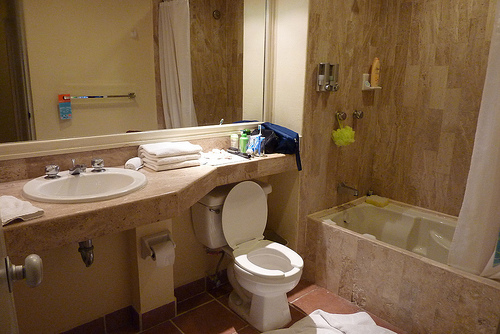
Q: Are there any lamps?
A: No, there are no lamps.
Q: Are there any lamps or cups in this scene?
A: No, there are no lamps or cups.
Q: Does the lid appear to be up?
A: Yes, the lid is up.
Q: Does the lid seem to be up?
A: Yes, the lid is up.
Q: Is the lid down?
A: No, the lid is up.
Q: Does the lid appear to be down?
A: No, the lid is up.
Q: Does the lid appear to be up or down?
A: The lid is up.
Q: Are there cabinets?
A: No, there are no cabinets.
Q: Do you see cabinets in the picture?
A: No, there are no cabinets.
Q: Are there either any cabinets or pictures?
A: No, there are no cabinets or pictures.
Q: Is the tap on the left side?
A: Yes, the tap is on the left of the image.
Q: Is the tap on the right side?
A: No, the tap is on the left of the image.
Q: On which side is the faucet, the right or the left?
A: The faucet is on the left of the image.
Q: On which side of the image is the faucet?
A: The faucet is on the left of the image.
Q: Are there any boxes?
A: No, there are no boxes.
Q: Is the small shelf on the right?
A: Yes, the shelf is on the right of the image.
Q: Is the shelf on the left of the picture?
A: No, the shelf is on the right of the image.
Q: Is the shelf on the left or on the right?
A: The shelf is on the right of the image.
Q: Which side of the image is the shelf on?
A: The shelf is on the right of the image.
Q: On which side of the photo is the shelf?
A: The shelf is on the right of the image.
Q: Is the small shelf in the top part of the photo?
A: Yes, the shelf is in the top of the image.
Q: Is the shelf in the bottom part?
A: No, the shelf is in the top of the image.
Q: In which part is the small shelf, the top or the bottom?
A: The shelf is in the top of the image.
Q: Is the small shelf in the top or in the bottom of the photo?
A: The shelf is in the top of the image.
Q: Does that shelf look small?
A: Yes, the shelf is small.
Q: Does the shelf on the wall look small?
A: Yes, the shelf is small.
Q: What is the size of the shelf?
A: The shelf is small.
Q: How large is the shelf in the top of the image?
A: The shelf is small.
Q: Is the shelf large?
A: No, the shelf is small.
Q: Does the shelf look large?
A: No, the shelf is small.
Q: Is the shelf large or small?
A: The shelf is small.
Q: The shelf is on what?
A: The shelf is on the wall.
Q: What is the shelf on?
A: The shelf is on the wall.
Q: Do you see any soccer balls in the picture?
A: No, there are no soccer balls.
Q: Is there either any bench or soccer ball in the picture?
A: No, there are no soccer balls or benches.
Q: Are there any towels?
A: Yes, there is a towel.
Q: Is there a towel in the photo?
A: Yes, there is a towel.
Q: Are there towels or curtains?
A: Yes, there is a towel.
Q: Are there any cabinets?
A: No, there are no cabinets.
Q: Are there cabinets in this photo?
A: No, there are no cabinets.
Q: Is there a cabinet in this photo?
A: No, there are no cabinets.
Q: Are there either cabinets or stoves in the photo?
A: No, there are no cabinets or stoves.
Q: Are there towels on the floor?
A: Yes, there is a towel on the floor.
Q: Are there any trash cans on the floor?
A: No, there is a towel on the floor.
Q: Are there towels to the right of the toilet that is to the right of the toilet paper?
A: Yes, there is a towel to the right of the toilet.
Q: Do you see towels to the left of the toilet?
A: No, the towel is to the right of the toilet.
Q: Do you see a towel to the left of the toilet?
A: No, the towel is to the right of the toilet.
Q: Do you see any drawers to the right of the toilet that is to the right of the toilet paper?
A: No, there is a towel to the right of the toilet.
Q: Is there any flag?
A: No, there are no flags.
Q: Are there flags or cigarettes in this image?
A: No, there are no flags or cigarettes.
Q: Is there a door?
A: Yes, there is a door.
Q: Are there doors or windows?
A: Yes, there is a door.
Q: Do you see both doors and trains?
A: No, there is a door but no trains.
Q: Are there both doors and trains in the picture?
A: No, there is a door but no trains.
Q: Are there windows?
A: No, there are no windows.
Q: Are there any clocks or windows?
A: No, there are no windows or clocks.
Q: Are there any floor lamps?
A: No, there are no floor lamps.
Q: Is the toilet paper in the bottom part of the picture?
A: Yes, the toilet paper is in the bottom of the image.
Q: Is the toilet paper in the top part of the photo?
A: No, the toilet paper is in the bottom of the image.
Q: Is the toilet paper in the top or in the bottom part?
A: The toilet paper is in the bottom of the image.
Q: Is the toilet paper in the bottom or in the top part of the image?
A: The toilet paper is in the bottom of the image.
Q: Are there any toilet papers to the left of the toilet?
A: Yes, there is a toilet paper to the left of the toilet.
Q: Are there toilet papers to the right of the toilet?
A: No, the toilet paper is to the left of the toilet.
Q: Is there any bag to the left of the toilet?
A: No, there is a toilet paper to the left of the toilet.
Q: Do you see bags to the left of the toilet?
A: No, there is a toilet paper to the left of the toilet.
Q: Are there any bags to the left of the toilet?
A: No, there is a toilet paper to the left of the toilet.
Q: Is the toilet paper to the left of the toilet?
A: Yes, the toilet paper is to the left of the toilet.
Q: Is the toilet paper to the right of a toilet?
A: No, the toilet paper is to the left of a toilet.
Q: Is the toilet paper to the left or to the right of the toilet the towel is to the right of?
A: The toilet paper is to the left of the toilet.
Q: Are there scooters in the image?
A: No, there are no scooters.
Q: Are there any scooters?
A: No, there are no scooters.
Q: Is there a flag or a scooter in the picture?
A: No, there are no scooters or flags.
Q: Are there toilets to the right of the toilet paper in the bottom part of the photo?
A: Yes, there is a toilet to the right of the toilet paper.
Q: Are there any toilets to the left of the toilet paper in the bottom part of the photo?
A: No, the toilet is to the right of the toilet paper.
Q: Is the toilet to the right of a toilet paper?
A: Yes, the toilet is to the right of a toilet paper.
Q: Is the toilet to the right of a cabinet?
A: No, the toilet is to the right of a toilet paper.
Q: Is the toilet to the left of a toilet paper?
A: No, the toilet is to the right of a toilet paper.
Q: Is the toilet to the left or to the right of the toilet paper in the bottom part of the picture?
A: The toilet is to the right of the toilet paper.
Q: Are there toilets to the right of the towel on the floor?
A: No, the toilet is to the left of the towel.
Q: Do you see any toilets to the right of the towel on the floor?
A: No, the toilet is to the left of the towel.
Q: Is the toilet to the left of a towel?
A: Yes, the toilet is to the left of a towel.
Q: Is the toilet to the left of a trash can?
A: No, the toilet is to the left of a towel.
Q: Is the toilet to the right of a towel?
A: No, the toilet is to the left of a towel.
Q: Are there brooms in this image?
A: No, there are no brooms.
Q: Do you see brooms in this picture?
A: No, there are no brooms.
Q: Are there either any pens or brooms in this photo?
A: No, there are no brooms or pens.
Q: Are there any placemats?
A: No, there are no placemats.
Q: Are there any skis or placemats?
A: No, there are no placemats or skis.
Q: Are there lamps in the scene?
A: No, there are no lamps.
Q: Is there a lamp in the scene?
A: No, there are no lamps.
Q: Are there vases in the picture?
A: No, there are no vases.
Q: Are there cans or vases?
A: No, there are no vases or cans.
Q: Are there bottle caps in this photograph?
A: No, there are no bottle caps.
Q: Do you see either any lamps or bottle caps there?
A: No, there are no bottle caps or lamps.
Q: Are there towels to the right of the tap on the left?
A: Yes, there are towels to the right of the tap.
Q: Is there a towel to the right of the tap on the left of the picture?
A: Yes, there are towels to the right of the tap.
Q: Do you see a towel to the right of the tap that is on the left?
A: Yes, there are towels to the right of the tap.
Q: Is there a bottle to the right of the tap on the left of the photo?
A: No, there are towels to the right of the tap.